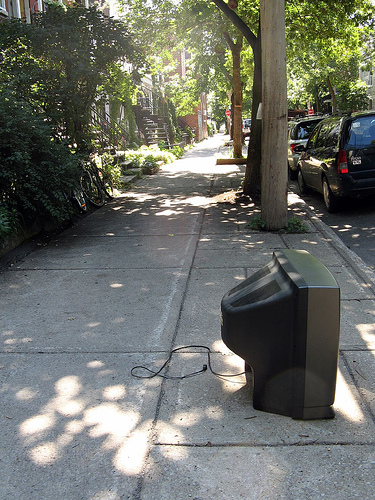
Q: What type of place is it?
A: It is a roadside.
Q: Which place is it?
A: It is a roadside.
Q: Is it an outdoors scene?
A: Yes, it is outdoors.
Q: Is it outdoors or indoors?
A: It is outdoors.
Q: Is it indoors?
A: No, it is outdoors.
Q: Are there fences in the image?
A: No, there are no fences.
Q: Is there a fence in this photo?
A: No, there are no fences.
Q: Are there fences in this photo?
A: No, there are no fences.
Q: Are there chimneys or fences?
A: No, there are no fences or chimneys.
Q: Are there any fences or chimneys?
A: No, there are no fences or chimneys.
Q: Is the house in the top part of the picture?
A: Yes, the house is in the top of the image.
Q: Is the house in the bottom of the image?
A: No, the house is in the top of the image.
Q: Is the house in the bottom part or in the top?
A: The house is in the top of the image.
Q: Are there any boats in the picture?
A: No, there are no boats.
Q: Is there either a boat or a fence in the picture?
A: No, there are no boats or fences.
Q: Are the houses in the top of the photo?
A: Yes, the houses are in the top of the image.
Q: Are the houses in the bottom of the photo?
A: No, the houses are in the top of the image.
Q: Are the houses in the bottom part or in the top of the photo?
A: The houses are in the top of the image.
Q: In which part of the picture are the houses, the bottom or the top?
A: The houses are in the top of the image.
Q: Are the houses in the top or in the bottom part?
A: The houses are in the top of the image.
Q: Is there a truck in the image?
A: No, there are no trucks.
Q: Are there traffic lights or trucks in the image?
A: No, there are no trucks or traffic lights.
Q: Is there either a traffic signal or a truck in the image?
A: No, there are no trucks or traffic lights.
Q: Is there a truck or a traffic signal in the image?
A: No, there are no trucks or traffic lights.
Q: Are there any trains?
A: No, there are no trains.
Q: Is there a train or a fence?
A: No, there are no trains or fences.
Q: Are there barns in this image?
A: No, there are no barns.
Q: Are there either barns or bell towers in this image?
A: No, there are no barns or bell towers.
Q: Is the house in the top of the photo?
A: Yes, the house is in the top of the image.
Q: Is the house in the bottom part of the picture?
A: No, the house is in the top of the image.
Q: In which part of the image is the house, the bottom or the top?
A: The house is in the top of the image.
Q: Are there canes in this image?
A: No, there are no canes.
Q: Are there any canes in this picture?
A: No, there are no canes.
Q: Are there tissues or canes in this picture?
A: No, there are no canes or tissues.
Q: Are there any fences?
A: No, there are no fences.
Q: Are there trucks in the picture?
A: No, there are no trucks.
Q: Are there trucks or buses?
A: No, there are no trucks or buses.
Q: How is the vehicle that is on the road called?
A: The vehicle is a car.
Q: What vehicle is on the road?
A: The vehicle is a car.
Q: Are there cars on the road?
A: Yes, there is a car on the road.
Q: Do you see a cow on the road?
A: No, there is a car on the road.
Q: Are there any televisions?
A: Yes, there is a television.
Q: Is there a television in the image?
A: Yes, there is a television.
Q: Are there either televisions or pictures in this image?
A: Yes, there is a television.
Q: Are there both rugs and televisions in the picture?
A: No, there is a television but no rugs.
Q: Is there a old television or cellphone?
A: Yes, there is an old television.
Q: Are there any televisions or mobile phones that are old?
A: Yes, the television is old.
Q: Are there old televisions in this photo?
A: Yes, there is an old television.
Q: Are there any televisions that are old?
A: Yes, there is a television that is old.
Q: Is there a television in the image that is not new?
A: Yes, there is a old television.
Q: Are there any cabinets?
A: No, there are no cabinets.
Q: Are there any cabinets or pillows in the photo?
A: No, there are no cabinets or pillows.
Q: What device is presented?
A: The device is a television.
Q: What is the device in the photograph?
A: The device is a television.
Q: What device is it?
A: The device is a television.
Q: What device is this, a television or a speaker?
A: This is a television.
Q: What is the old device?
A: The device is a television.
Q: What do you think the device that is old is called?
A: The device is a television.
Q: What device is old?
A: The device is a television.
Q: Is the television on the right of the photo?
A: Yes, the television is on the right of the image.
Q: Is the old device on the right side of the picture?
A: Yes, the television is on the right of the image.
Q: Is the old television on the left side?
A: No, the TV is on the right of the image.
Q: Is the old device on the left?
A: No, the TV is on the right of the image.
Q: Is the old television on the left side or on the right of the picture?
A: The television is on the right of the image.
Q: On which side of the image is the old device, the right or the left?
A: The television is on the right of the image.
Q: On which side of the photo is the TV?
A: The TV is on the right of the image.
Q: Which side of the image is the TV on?
A: The TV is on the right of the image.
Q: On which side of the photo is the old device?
A: The TV is on the right of the image.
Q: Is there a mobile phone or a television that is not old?
A: No, there is a television but it is old.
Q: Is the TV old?
A: Yes, the TV is old.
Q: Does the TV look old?
A: Yes, the TV is old.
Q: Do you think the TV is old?
A: Yes, the TV is old.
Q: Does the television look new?
A: No, the television is old.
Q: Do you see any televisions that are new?
A: No, there is a television but it is old.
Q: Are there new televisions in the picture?
A: No, there is a television but it is old.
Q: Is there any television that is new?
A: No, there is a television but it is old.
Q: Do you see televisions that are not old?
A: No, there is a television but it is old.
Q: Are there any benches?
A: No, there are no benches.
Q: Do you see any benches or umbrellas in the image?
A: No, there are no benches or umbrellas.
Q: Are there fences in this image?
A: No, there are no fences.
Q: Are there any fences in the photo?
A: No, there are no fences.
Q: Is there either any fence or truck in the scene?
A: No, there are no fences or trucks.